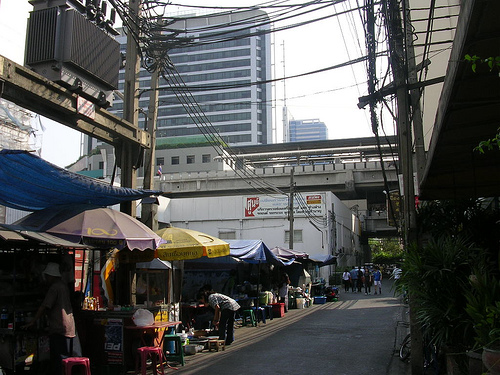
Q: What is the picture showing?
A: It is showing a market.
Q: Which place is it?
A: It is a market.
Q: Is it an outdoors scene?
A: Yes, it is outdoors.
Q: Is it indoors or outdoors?
A: It is outdoors.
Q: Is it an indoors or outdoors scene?
A: It is outdoors.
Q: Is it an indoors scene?
A: No, it is outdoors.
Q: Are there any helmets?
A: No, there are no helmets.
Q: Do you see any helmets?
A: No, there are no helmets.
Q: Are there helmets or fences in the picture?
A: No, there are no helmets or fences.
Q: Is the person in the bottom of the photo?
A: Yes, the person is in the bottom of the image.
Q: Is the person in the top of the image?
A: No, the person is in the bottom of the image.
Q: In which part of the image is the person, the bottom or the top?
A: The person is in the bottom of the image.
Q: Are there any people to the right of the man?
A: Yes, there is a person to the right of the man.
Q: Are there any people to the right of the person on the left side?
A: Yes, there is a person to the right of the man.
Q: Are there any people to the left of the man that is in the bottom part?
A: No, the person is to the right of the man.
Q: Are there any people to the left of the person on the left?
A: No, the person is to the right of the man.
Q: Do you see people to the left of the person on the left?
A: No, the person is to the right of the man.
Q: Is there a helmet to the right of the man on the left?
A: No, there is a person to the right of the man.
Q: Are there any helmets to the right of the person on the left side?
A: No, there is a person to the right of the man.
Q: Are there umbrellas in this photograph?
A: Yes, there is an umbrella.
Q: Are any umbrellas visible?
A: Yes, there is an umbrella.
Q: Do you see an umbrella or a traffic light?
A: Yes, there is an umbrella.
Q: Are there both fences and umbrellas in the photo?
A: No, there is an umbrella but no fences.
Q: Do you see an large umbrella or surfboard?
A: Yes, there is a large umbrella.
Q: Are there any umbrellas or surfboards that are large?
A: Yes, the umbrella is large.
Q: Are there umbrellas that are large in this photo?
A: Yes, there is a large umbrella.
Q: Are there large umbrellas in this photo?
A: Yes, there is a large umbrella.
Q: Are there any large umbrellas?
A: Yes, there is a large umbrella.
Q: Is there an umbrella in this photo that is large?
A: Yes, there is an umbrella that is large.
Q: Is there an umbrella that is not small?
A: Yes, there is a large umbrella.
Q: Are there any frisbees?
A: No, there are no frisbees.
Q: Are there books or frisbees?
A: No, there are no frisbees or books.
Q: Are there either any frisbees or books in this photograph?
A: No, there are no frisbees or books.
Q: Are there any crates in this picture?
A: No, there are no crates.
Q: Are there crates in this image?
A: No, there are no crates.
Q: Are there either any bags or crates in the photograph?
A: No, there are no crates or bags.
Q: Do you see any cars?
A: No, there are no cars.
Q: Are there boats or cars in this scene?
A: No, there are no cars or boats.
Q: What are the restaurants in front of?
A: The restaurants are in front of the building.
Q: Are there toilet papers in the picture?
A: No, there are no toilet papers.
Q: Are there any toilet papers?
A: No, there are no toilet papers.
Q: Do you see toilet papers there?
A: No, there are no toilet papers.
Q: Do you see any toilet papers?
A: No, there are no toilet papers.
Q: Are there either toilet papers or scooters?
A: No, there are no toilet papers or scooters.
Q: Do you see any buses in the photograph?
A: No, there are no buses.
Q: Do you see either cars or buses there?
A: No, there are no buses or cars.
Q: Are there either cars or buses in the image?
A: No, there are no buses or cars.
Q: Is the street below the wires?
A: Yes, the street is below the wires.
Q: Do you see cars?
A: No, there are no cars.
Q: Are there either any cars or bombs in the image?
A: No, there are no cars or bombs.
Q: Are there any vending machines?
A: No, there are no vending machines.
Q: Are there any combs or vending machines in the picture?
A: No, there are no vending machines or combs.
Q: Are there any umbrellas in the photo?
A: Yes, there is an umbrella.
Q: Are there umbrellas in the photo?
A: Yes, there is an umbrella.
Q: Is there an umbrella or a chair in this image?
A: Yes, there is an umbrella.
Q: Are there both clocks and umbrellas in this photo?
A: No, there is an umbrella but no clocks.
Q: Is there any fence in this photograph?
A: No, there are no fences.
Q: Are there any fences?
A: No, there are no fences.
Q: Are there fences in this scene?
A: No, there are no fences.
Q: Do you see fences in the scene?
A: No, there are no fences.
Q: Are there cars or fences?
A: No, there are no fences or cars.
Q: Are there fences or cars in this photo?
A: No, there are no fences or cars.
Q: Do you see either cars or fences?
A: No, there are no fences or cars.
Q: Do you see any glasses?
A: No, there are no glasses.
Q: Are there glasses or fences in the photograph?
A: No, there are no glasses or fences.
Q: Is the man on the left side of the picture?
A: Yes, the man is on the left of the image.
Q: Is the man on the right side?
A: No, the man is on the left of the image.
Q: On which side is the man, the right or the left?
A: The man is on the left of the image.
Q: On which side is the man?
A: The man is on the left of the image.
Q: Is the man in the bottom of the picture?
A: Yes, the man is in the bottom of the image.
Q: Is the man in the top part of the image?
A: No, the man is in the bottom of the image.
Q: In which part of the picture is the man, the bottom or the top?
A: The man is in the bottom of the image.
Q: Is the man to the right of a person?
A: No, the man is to the left of a person.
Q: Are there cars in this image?
A: No, there are no cars.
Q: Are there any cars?
A: No, there are no cars.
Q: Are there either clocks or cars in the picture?
A: No, there are no cars or clocks.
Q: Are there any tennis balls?
A: No, there are no tennis balls.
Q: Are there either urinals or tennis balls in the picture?
A: No, there are no tennis balls or urinals.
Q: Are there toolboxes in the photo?
A: No, there are no toolboxes.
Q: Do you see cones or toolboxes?
A: No, there are no toolboxes or cones.